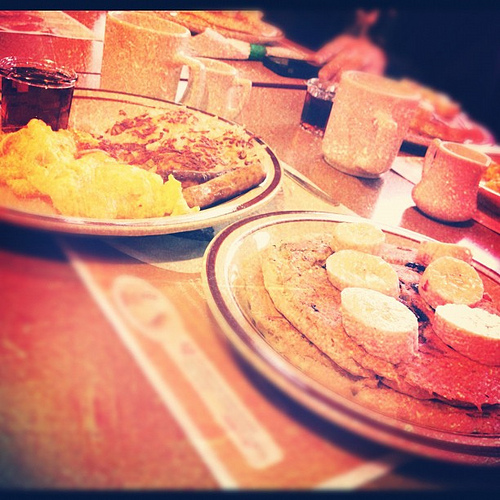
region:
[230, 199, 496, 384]
pancakes with bananas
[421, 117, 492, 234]
small creamer mug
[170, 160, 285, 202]
browned link sausage on plate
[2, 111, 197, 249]
scrambled eggs on plate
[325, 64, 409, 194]
speckled coffee mug with handle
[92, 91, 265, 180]
golden brown hashbrowns on plate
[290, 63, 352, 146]
clear glass cup of syrup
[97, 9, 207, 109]
speckled coffee mug with handle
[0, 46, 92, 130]
clear glass cup with syrup in it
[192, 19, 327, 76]
napkin folding with utensils in it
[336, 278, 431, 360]
Slice of banana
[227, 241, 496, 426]
Banana slices on pancakes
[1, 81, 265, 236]
Maple syrup, eggs and potatoes on plate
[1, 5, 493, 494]
Different breakfast options on plates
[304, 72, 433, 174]
White coffee cup on table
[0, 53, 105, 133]
Cup of maple syrup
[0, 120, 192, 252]
yellow scrambled eggs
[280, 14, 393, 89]
hand of person eating at table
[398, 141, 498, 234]
white creamer cup for coffee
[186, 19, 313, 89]
Silverware wrapped in a napkin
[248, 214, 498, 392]
pancakes with banana slices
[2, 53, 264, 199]
scrambled eggs with hashbrowns and syrup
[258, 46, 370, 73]
customer's white hand and black cell phone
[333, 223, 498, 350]
six yellow banana slices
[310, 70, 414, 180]
small cup of syrup and a white coffee cup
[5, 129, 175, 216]
fluffy yellow scrambled eggs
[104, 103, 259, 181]
golden fried hashbrowns and a sausage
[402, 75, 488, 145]
pancakes topped with butter and syrup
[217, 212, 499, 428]
two pancakes with six banana slices breakfast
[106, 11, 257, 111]
big white coffee cup with small creamer cup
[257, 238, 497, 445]
the plate has pancakes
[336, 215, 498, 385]
the pancakes have bananas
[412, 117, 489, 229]
cup of syrup on the table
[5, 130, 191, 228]
this plate has eggs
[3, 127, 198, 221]
the eggs are yellow and flurry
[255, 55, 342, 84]
a cellphone on the table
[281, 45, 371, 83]
a hand on the cellphone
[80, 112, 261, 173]
hashbrowns by the eggs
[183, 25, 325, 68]
silver ware wrapped in a napkin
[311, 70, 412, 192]
coffee cup is white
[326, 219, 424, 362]
three slices of banana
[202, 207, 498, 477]
plate of pancakes with bananas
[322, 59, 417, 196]
white ceramic mug on table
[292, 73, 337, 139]
clear glass of syrup on table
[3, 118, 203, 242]
scrambled eggs on a plate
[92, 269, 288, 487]
drawing of a spoon on table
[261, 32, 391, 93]
hand on a phone on table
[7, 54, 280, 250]
plate of eggs and hashbrowns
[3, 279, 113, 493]
wooden table where food is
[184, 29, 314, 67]
napkin rolled in green paper on table